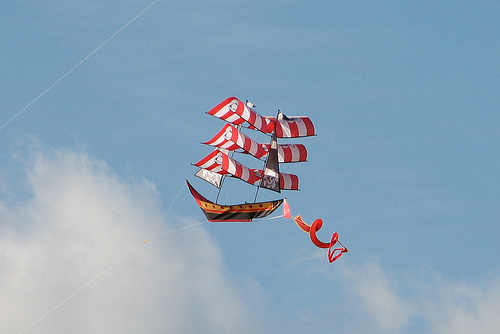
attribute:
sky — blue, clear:
[2, 1, 500, 334]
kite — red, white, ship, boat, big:
[187, 96, 351, 264]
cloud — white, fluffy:
[0, 159, 232, 332]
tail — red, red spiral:
[282, 200, 348, 263]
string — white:
[15, 185, 200, 333]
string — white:
[2, 2, 156, 132]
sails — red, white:
[195, 96, 316, 192]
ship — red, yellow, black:
[185, 180, 285, 222]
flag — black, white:
[262, 126, 281, 194]